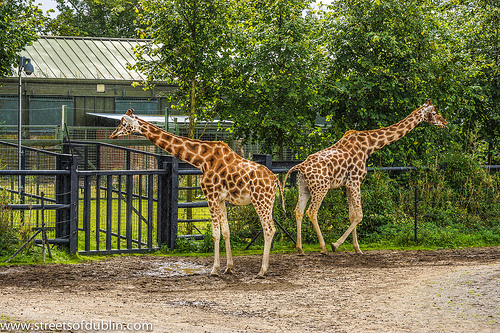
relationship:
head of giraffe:
[104, 109, 143, 138] [108, 107, 285, 276]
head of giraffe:
[423, 98, 445, 127] [283, 96, 449, 256]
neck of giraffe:
[376, 108, 426, 147] [283, 96, 449, 256]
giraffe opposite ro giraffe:
[283, 96, 449, 256] [108, 107, 285, 276]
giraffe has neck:
[108, 107, 285, 276] [138, 119, 209, 163]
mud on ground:
[141, 258, 214, 280] [0, 247, 496, 331]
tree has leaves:
[128, 0, 260, 232] [177, 19, 220, 69]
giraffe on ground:
[108, 107, 285, 276] [0, 247, 496, 331]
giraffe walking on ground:
[283, 96, 449, 256] [0, 247, 496, 331]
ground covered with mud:
[0, 247, 496, 331] [0, 250, 497, 290]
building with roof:
[1, 34, 324, 182] [4, 39, 246, 81]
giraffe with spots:
[108, 107, 285, 276] [328, 160, 346, 180]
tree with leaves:
[124, 0, 250, 233] [182, 36, 269, 93]